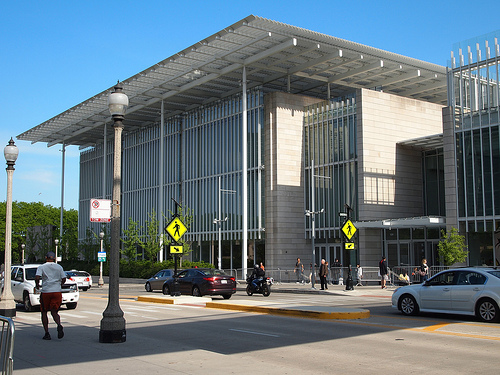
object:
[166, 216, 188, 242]
crosswalk sign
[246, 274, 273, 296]
motorcycle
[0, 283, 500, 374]
road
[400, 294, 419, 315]
tire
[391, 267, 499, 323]
car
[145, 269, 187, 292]
car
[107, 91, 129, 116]
light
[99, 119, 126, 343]
pole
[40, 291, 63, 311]
shorts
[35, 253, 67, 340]
man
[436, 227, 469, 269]
tree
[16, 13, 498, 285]
building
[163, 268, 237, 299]
car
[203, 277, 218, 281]
tail light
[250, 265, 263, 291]
man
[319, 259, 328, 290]
people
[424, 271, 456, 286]
windows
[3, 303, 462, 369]
shadow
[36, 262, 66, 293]
shirt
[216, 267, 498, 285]
fence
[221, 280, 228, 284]
license plate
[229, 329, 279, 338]
line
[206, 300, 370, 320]
curb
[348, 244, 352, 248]
arrow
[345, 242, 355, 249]
sign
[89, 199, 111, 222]
sign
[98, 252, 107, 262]
sign